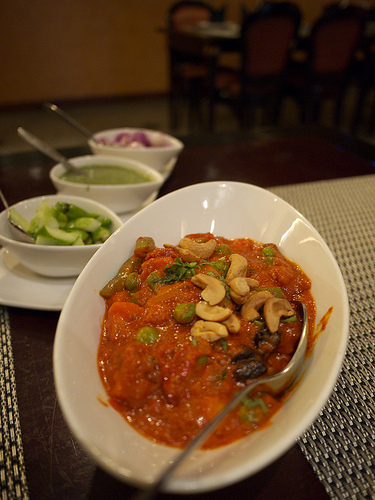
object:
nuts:
[162, 243, 199, 263]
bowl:
[53, 181, 349, 493]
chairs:
[290, 0, 373, 131]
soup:
[98, 234, 314, 451]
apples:
[34, 224, 80, 246]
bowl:
[0, 194, 125, 278]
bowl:
[88, 126, 185, 171]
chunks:
[92, 226, 112, 243]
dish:
[160, 156, 178, 181]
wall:
[0, 0, 136, 87]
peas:
[125, 274, 137, 290]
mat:
[327, 174, 364, 216]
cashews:
[195, 301, 233, 322]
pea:
[173, 302, 195, 324]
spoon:
[50, 104, 98, 143]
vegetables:
[100, 236, 156, 299]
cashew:
[191, 273, 226, 306]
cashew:
[264, 297, 295, 334]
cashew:
[179, 237, 217, 259]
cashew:
[190, 320, 229, 342]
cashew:
[228, 277, 250, 296]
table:
[339, 186, 374, 222]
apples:
[65, 216, 102, 232]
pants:
[163, 257, 198, 283]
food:
[235, 390, 269, 415]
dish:
[54, 190, 158, 227]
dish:
[0, 246, 80, 311]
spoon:
[140, 300, 309, 498]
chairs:
[210, 2, 302, 133]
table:
[169, 19, 310, 110]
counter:
[23, 393, 57, 462]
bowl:
[49, 154, 165, 214]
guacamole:
[59, 163, 156, 184]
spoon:
[16, 126, 86, 176]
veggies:
[9, 208, 30, 233]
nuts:
[230, 288, 258, 304]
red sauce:
[112, 360, 143, 404]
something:
[91, 128, 170, 147]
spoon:
[0, 192, 35, 244]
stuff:
[107, 301, 143, 321]